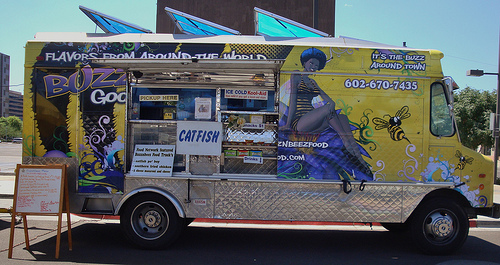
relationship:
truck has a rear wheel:
[21, 7, 494, 255] [119, 193, 180, 250]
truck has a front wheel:
[21, 7, 494, 255] [410, 197, 469, 255]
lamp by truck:
[467, 67, 485, 78] [21, 7, 494, 255]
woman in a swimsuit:
[277, 57, 370, 175] [290, 75, 321, 136]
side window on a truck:
[128, 85, 281, 127] [21, 7, 494, 255]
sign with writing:
[176, 121, 222, 156] [180, 130, 220, 144]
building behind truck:
[156, 0, 336, 37] [21, 7, 494, 255]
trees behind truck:
[433, 87, 500, 158] [21, 7, 494, 255]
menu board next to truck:
[7, 164, 73, 258] [21, 7, 494, 255]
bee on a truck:
[373, 105, 412, 145] [21, 7, 494, 255]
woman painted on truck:
[277, 57, 370, 175] [21, 7, 494, 255]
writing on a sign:
[180, 130, 220, 144] [176, 121, 222, 156]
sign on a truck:
[176, 121, 222, 156] [21, 7, 494, 255]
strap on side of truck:
[187, 179, 191, 203] [21, 7, 494, 255]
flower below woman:
[277, 102, 374, 184] [277, 57, 370, 175]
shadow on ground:
[23, 222, 499, 262] [0, 142, 499, 262]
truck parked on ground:
[21, 7, 494, 255] [0, 142, 499, 262]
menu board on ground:
[7, 164, 73, 258] [0, 142, 499, 262]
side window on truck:
[128, 85, 281, 127] [21, 7, 494, 255]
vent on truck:
[79, 6, 332, 39] [21, 7, 494, 255]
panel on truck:
[66, 174, 453, 225] [21, 7, 494, 255]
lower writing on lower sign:
[135, 148, 174, 156] [130, 144, 176, 177]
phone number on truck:
[345, 79, 419, 90] [21, 7, 494, 255]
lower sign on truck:
[130, 144, 176, 177] [21, 7, 494, 255]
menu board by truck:
[7, 164, 73, 258] [21, 7, 494, 255]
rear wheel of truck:
[119, 193, 180, 250] [21, 7, 494, 255]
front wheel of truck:
[410, 197, 469, 255] [21, 7, 494, 255]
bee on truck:
[373, 105, 412, 145] [21, 7, 494, 255]